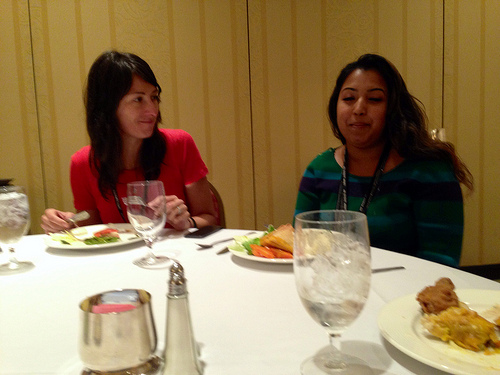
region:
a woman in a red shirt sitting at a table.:
[35, 50, 226, 233]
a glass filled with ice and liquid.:
[267, 196, 389, 368]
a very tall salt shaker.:
[156, 242, 216, 372]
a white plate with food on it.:
[375, 275, 495, 365]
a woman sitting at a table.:
[40, 48, 231, 240]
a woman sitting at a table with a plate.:
[285, 45, 465, 270]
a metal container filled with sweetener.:
[70, 270, 166, 370]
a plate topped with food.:
[220, 211, 345, 271]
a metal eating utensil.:
[312, 256, 414, 316]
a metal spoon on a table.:
[182, 224, 242, 254]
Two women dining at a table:
[24, 23, 468, 275]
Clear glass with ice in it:
[280, 201, 375, 371]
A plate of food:
[231, 208, 319, 270]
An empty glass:
[114, 169, 188, 267]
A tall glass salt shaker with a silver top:
[156, 257, 216, 373]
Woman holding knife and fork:
[39, 63, 211, 231]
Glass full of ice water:
[2, 151, 50, 281]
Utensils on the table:
[194, 223, 259, 261]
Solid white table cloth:
[191, 259, 313, 374]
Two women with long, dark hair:
[59, 33, 465, 198]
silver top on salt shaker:
[155, 260, 210, 300]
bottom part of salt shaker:
[168, 297, 200, 374]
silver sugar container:
[82, 287, 159, 374]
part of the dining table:
[215, 269, 277, 328]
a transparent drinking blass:
[286, 210, 368, 373]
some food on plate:
[414, 286, 498, 353]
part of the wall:
[188, 41, 295, 116]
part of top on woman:
[423, 182, 464, 239]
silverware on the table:
[194, 220, 235, 257]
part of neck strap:
[338, 141, 388, 193]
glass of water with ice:
[280, 203, 374, 373]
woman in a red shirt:
[52, 34, 234, 236]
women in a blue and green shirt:
[290, 34, 484, 206]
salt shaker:
[157, 252, 210, 372]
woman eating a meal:
[44, 46, 225, 261]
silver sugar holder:
[62, 266, 162, 373]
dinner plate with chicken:
[383, 253, 496, 363]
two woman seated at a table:
[30, 30, 470, 291]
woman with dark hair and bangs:
[30, 23, 233, 264]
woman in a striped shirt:
[266, 48, 467, 290]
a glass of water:
[278, 191, 398, 373]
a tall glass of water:
[272, 199, 412, 363]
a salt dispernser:
[147, 250, 222, 373]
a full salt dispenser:
[135, 254, 229, 353]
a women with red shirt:
[64, 31, 241, 246]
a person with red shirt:
[27, 14, 232, 253]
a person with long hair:
[303, 23, 495, 306]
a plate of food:
[210, 198, 322, 300]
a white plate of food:
[236, 190, 346, 303]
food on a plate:
[199, 199, 374, 314]